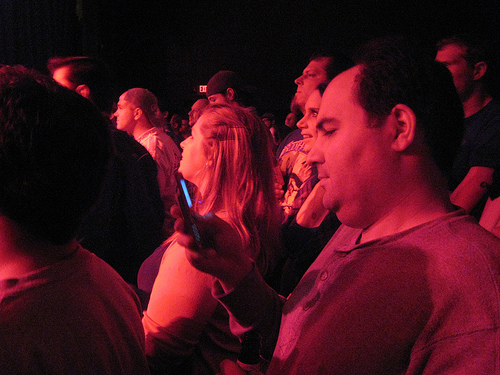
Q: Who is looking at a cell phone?
A: A man.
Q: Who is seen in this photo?
A: Men and women.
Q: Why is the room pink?
A: Because the people are at an entertainment event.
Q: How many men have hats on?
A: Two.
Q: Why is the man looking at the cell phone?
A: He is viewing information on the cell phone.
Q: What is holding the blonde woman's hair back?
A: Hair pins.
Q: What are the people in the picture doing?
A: Sitting on chairs.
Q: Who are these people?
A: They are viewers of some show.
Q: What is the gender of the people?
A: There are men and women, both.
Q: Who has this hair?
A: The woman.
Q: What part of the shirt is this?
A: Collar.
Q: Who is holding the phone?
A: The man.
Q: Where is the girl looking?
A: Up.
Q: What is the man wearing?
A: A shirt.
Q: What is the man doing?
A: Texting.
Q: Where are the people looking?
A: Up.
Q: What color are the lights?
A: Red.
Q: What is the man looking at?
A: His phone.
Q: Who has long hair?
A: The woman.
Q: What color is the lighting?
A: Red.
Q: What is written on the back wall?
A: Exit.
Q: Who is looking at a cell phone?
A: The man in front.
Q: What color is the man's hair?
A: Black.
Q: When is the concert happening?
A: Night time.